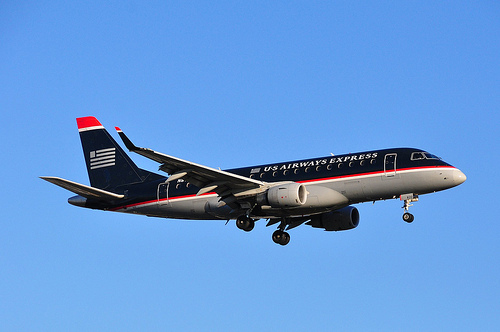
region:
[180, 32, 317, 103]
blue sky behind plane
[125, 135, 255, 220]
wing of the plane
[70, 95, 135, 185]
tail of the plane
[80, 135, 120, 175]
flag symbol on the tail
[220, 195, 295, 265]
tires on bottom of plane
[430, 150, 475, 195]
nose of the plane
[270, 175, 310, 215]
engine on the plane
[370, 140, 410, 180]
door of the plane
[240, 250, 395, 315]
clear sky in the photo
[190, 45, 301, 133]
this is the sky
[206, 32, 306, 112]
the sky is blue in color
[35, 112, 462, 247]
this is a jet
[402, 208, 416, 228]
this is the wheel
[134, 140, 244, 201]
this is the wing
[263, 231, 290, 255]
this is the hind wheel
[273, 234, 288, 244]
the wheel is black in color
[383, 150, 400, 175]
this is a door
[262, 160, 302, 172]
this is a writing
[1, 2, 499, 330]
A plane in the sky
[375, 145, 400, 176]
A door on the plane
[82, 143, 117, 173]
Flag drawing on the plane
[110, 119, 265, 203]
A wing of the plane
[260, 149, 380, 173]
White words on side of the plane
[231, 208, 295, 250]
Black and round wheels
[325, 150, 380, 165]
The word "EXPRESS" on the plane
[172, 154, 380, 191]
Windows on side of the plane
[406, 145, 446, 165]
Windows on front of the plane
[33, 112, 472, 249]
A blue, gray and red airplane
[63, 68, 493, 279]
plane in the sky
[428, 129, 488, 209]
front of the plane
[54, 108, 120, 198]
tail of the plane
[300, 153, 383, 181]
windows on side of plane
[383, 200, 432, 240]
wheel under the plane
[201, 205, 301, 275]
wheels under the plane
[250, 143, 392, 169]
words on side of plane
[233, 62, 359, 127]
blue sky in the background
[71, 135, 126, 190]
flag icon on back of plane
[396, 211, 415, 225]
the front wheels are down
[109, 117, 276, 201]
the right wing of the plane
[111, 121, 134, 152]
the wing tip is raised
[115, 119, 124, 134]
the wing tip is red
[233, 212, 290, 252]
these wheels are lowered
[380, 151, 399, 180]
the door of the plane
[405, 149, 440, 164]
windows on the cockpit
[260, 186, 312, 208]
right propeller on the plane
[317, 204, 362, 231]
left propeller on the plane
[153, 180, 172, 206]
the back door on the plane